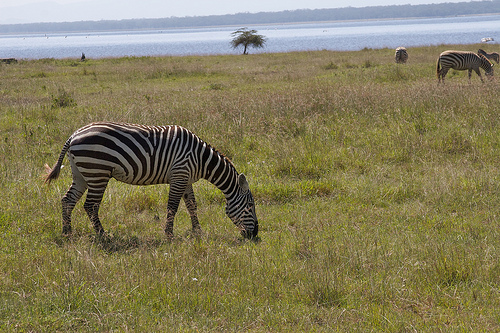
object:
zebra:
[44, 121, 258, 239]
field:
[0, 42, 497, 333]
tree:
[229, 26, 266, 55]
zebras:
[436, 50, 494, 85]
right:
[276, 0, 500, 333]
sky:
[0, 1, 480, 26]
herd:
[395, 47, 409, 63]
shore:
[0, 28, 500, 64]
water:
[0, 14, 500, 58]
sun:
[6, 2, 21, 8]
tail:
[43, 137, 75, 186]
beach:
[0, 40, 499, 65]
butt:
[67, 124, 106, 163]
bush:
[49, 82, 77, 109]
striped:
[90, 134, 205, 171]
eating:
[239, 221, 259, 242]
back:
[63, 121, 209, 150]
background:
[0, 0, 500, 61]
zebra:
[477, 49, 500, 65]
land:
[1, 0, 500, 33]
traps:
[481, 37, 495, 43]